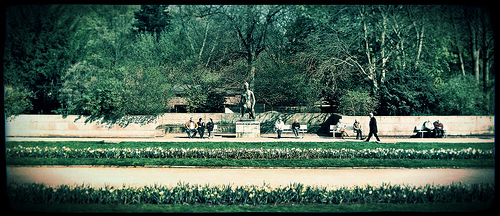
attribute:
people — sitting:
[163, 113, 464, 143]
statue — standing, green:
[219, 79, 268, 123]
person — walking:
[359, 107, 389, 147]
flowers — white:
[11, 139, 499, 160]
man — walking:
[347, 109, 385, 151]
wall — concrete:
[1, 111, 499, 149]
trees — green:
[16, 8, 498, 115]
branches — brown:
[305, 10, 438, 100]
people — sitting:
[172, 99, 219, 145]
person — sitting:
[270, 104, 285, 144]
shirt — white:
[271, 119, 284, 132]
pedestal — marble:
[231, 115, 268, 156]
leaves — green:
[373, 60, 452, 119]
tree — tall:
[219, 12, 275, 108]